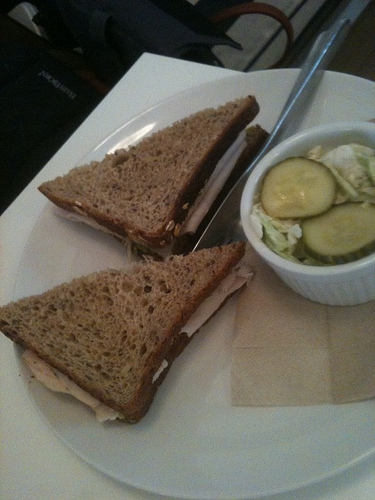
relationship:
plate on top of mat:
[13, 68, 375, 500] [0, 51, 373, 498]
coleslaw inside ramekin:
[248, 143, 374, 267] [239, 121, 374, 306]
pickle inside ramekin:
[259, 156, 338, 220] [239, 121, 374, 306]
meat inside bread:
[178, 261, 255, 336] [37, 96, 261, 249]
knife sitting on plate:
[192, 17, 353, 253] [13, 68, 375, 500]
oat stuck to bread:
[166, 221, 175, 233] [36, 93, 261, 248]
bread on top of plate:
[37, 96, 261, 249] [13, 68, 375, 500]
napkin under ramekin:
[228, 238, 374, 406] [239, 121, 374, 306]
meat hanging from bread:
[178, 261, 255, 336] [37, 96, 261, 249]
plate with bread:
[13, 68, 375, 500] [37, 96, 261, 249]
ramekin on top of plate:
[239, 121, 374, 306] [13, 68, 375, 500]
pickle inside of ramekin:
[259, 156, 338, 220] [239, 121, 374, 306]